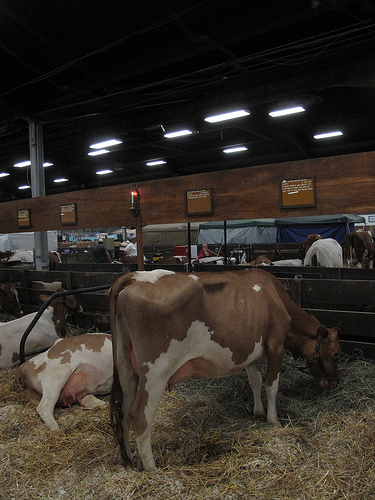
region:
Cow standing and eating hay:
[105, 270, 342, 472]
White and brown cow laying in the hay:
[15, 331, 118, 432]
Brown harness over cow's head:
[289, 324, 344, 388]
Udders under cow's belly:
[57, 370, 89, 408]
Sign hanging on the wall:
[277, 175, 318, 210]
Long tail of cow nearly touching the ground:
[110, 272, 134, 471]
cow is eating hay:
[116, 262, 352, 433]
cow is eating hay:
[277, 293, 369, 425]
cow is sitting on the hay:
[15, 318, 150, 442]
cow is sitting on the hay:
[5, 293, 75, 381]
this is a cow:
[82, 242, 355, 490]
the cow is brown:
[86, 218, 351, 479]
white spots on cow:
[124, 306, 263, 402]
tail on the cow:
[92, 266, 155, 470]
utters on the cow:
[41, 365, 96, 413]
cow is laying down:
[17, 303, 139, 451]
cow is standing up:
[81, 237, 364, 472]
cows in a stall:
[17, 212, 372, 497]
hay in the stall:
[34, 283, 358, 498]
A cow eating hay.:
[106, 263, 342, 470]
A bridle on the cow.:
[309, 321, 330, 384]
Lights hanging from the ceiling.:
[82, 99, 344, 176]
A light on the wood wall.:
[127, 182, 141, 220]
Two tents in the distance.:
[200, 216, 367, 239]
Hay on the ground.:
[192, 416, 373, 497]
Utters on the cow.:
[56, 369, 88, 408]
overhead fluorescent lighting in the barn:
[204, 108, 249, 125]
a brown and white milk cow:
[106, 268, 341, 476]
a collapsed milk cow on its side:
[15, 329, 110, 438]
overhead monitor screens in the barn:
[278, 174, 316, 212]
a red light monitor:
[127, 182, 139, 214]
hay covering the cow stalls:
[0, 430, 373, 497]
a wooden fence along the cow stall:
[291, 264, 374, 311]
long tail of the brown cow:
[107, 272, 132, 476]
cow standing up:
[107, 267, 348, 477]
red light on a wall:
[128, 185, 140, 214]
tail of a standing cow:
[110, 275, 131, 469]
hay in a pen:
[0, 310, 374, 498]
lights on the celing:
[57, 78, 321, 203]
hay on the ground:
[276, 407, 362, 485]